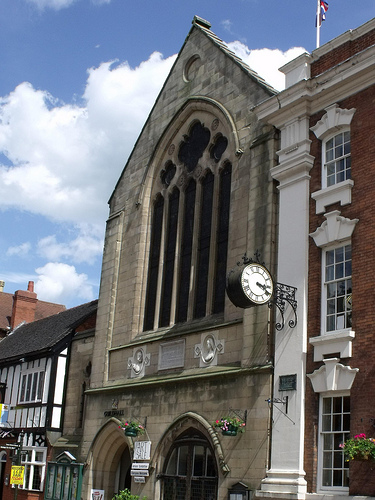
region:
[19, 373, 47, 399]
the windows of a building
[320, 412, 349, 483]
the window of a building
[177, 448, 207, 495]
the windows of a building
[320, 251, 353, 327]
the window of a building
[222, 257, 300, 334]
a clock on the side of a building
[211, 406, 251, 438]
flowers hanging on the side of a building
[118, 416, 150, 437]
flowers hanging on the side of a building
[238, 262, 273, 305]
the face of a clock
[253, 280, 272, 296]
the hands on a clock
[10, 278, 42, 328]
the brick chimney of a building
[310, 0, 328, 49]
a flag on top of the building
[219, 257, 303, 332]
a clock attached to the side of the building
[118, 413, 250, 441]
two hanging plants attached to the side of the building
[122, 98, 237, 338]
a large arched window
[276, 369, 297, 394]
a black sign on the side of the building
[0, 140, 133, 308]
a blue sky with some clouds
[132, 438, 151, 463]
an Art Sale sign on the front of the building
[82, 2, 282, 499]
a large old stone building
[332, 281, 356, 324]
a reflection of the clock in the window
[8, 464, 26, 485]
a yellow sign on the window of a building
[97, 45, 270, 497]
big brown church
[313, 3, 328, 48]
white pole with flag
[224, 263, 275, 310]
black and white clock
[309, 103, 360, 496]
white windows on brick building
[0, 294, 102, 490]
black and white house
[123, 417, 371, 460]
flowerpots on the wall with pink flowers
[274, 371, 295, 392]
black signboard on white wall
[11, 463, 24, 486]
squared yellow signboard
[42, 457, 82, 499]
green windows on wall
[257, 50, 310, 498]
white column between buildings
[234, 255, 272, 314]
clock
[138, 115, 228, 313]
window in brown building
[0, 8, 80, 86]
white clouds in blue sky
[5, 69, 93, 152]
white clouds in blue sky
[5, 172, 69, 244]
white clouds in blue sky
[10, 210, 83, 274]
white clouds in blue sky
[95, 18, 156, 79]
white clouds in blue sky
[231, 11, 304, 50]
white clouds in blue sky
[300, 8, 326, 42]
flag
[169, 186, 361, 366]
a clock extending from building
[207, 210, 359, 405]
a black and white clock extending from building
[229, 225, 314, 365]
a black and white clock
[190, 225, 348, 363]
a black and white outside clock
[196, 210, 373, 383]
a clock on an old building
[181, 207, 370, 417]
an outside clock on an old building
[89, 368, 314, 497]
plants hanging on the building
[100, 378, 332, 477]
plants hangin on the outside of a building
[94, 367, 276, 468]
plants hanging on an old building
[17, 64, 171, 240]
blue sky with white clouds